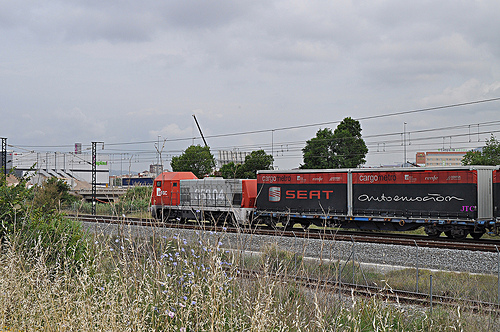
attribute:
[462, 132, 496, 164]
tree — green, large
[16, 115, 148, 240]
building — blue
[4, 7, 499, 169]
sky — cloudy, grey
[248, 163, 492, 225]
cart — black, red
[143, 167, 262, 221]
engine — silver, red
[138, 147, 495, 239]
train — gray, orange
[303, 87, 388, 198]
tree — green, large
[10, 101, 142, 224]
structure — white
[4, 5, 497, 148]
sky — cloudy, overcast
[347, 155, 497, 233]
car — black, red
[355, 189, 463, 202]
writing — white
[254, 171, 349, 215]
background — dark